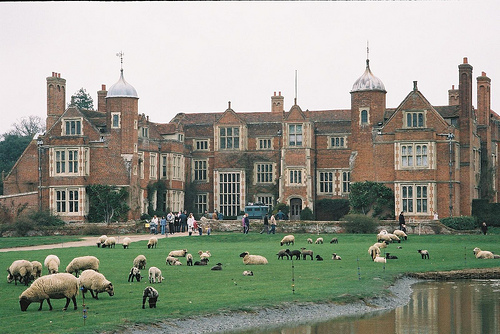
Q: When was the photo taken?
A: Daytime.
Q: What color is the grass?
A: Green.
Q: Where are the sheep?
A: On the lawn.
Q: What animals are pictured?
A: Sheep.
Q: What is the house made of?
A: Brick.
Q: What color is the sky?
A: Grey.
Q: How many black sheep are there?
A: Eight.